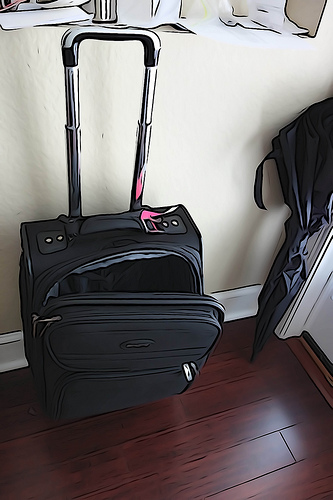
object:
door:
[299, 271, 332, 387]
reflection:
[134, 164, 146, 201]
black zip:
[48, 363, 193, 422]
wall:
[0, 0, 332, 337]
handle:
[60, 18, 161, 220]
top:
[19, 205, 217, 319]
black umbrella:
[249, 97, 332, 366]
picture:
[0, 0, 327, 41]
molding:
[0, 283, 263, 376]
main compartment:
[34, 247, 226, 425]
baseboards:
[0, 282, 263, 374]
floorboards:
[273, 412, 332, 463]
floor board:
[209, 282, 265, 325]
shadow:
[0, 373, 211, 499]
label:
[140, 204, 180, 221]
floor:
[0, 314, 332, 499]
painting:
[0, 0, 326, 41]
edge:
[0, 15, 320, 40]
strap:
[251, 152, 274, 211]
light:
[204, 394, 333, 498]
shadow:
[221, 68, 332, 291]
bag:
[17, 204, 228, 432]